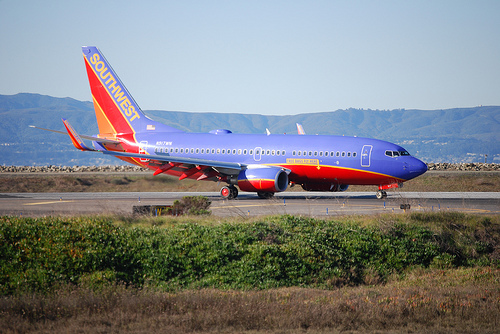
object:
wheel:
[217, 184, 238, 199]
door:
[251, 146, 261, 161]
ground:
[0, 189, 497, 215]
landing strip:
[0, 191, 497, 210]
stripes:
[83, 52, 141, 155]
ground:
[0, 192, 498, 333]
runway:
[1, 191, 499, 216]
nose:
[407, 156, 432, 183]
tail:
[80, 44, 153, 136]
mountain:
[0, 98, 499, 162]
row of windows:
[152, 146, 260, 155]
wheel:
[373, 191, 386, 200]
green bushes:
[0, 212, 499, 283]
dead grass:
[20, 281, 495, 328]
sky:
[1, 0, 499, 106]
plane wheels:
[372, 187, 388, 201]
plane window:
[150, 147, 160, 154]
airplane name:
[88, 52, 142, 121]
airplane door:
[359, 144, 373, 168]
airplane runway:
[7, 189, 499, 216]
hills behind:
[0, 89, 499, 166]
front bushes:
[2, 215, 498, 280]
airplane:
[53, 43, 430, 216]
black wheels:
[374, 190, 387, 199]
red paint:
[82, 57, 131, 133]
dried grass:
[1, 283, 499, 333]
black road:
[6, 189, 499, 219]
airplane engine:
[235, 167, 288, 193]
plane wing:
[58, 117, 242, 179]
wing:
[56, 117, 242, 170]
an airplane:
[27, 46, 429, 200]